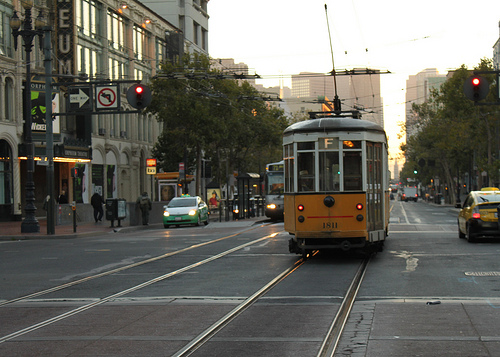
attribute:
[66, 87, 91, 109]
street signs — in the picture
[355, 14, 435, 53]
sky — white , cloudy 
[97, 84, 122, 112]
arrow — black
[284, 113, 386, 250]
streetcar — in the picture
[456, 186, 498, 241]
cab — in the picture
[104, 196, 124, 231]
people — in the picture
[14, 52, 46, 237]
pole — black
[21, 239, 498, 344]
street — asphalt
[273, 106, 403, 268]
trolley — yellow, white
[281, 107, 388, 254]
trolley — yellow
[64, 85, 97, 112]
arrow — white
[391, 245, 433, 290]
arrow — white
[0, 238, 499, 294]
asphalt surface — black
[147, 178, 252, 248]
cab — green , white 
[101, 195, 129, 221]
newspaper box — in the picture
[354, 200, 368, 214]
light — red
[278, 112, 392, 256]
streetcar — orange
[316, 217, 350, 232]
number — black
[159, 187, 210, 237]
cab — white, green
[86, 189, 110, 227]
person — in the picture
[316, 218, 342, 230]
numbers — black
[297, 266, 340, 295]
surface — black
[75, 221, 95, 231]
surface — red, brick